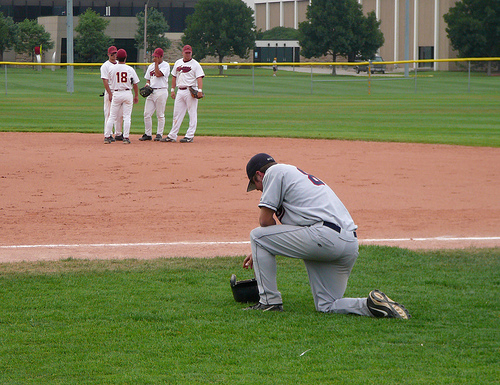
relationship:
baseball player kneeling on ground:
[241, 154, 417, 323] [6, 63, 500, 382]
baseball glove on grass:
[229, 279, 263, 308] [12, 246, 500, 384]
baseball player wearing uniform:
[241, 154, 417, 323] [252, 159, 357, 228]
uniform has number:
[109, 62, 141, 93] [116, 70, 130, 83]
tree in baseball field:
[296, 2, 385, 78] [4, 59, 499, 378]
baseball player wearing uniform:
[96, 44, 140, 137] [109, 62, 141, 93]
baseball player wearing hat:
[241, 154, 417, 323] [238, 152, 278, 192]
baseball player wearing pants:
[241, 154, 417, 323] [251, 215, 376, 318]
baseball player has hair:
[241, 154, 417, 323] [254, 157, 276, 175]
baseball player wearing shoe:
[241, 154, 417, 323] [365, 289, 408, 328]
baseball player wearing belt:
[241, 154, 417, 323] [322, 218, 358, 241]